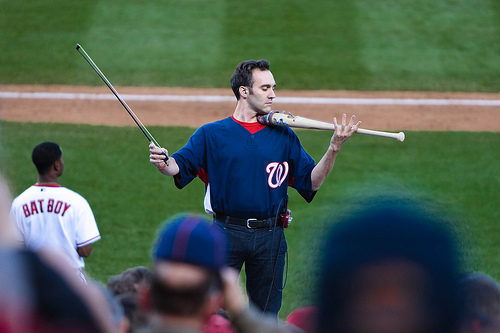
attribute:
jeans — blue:
[186, 209, 337, 316]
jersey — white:
[10, 180, 103, 271]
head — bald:
[139, 255, 222, 322]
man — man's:
[148, 57, 359, 310]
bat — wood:
[233, 71, 410, 148]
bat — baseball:
[253, 108, 410, 146]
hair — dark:
[240, 57, 265, 72]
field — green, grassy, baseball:
[9, 4, 495, 288]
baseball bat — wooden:
[253, 94, 415, 147]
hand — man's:
[323, 114, 365, 154]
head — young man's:
[15, 136, 73, 181]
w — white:
[262, 157, 289, 193]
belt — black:
[213, 212, 287, 229]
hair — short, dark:
[30, 141, 65, 170]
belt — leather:
[230, 215, 308, 222]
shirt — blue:
[168, 118, 319, 225]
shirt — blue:
[190, 101, 334, 215]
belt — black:
[204, 197, 284, 237]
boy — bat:
[28, 134, 126, 254]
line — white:
[44, 67, 174, 117]